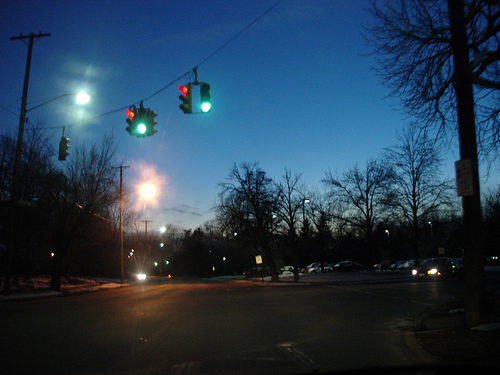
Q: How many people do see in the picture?
A: None.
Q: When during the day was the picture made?
A: At night.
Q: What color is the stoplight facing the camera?
A: Green.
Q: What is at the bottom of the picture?
A: A road.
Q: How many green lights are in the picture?
A: Two.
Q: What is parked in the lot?
A: Automobiles.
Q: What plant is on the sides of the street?
A: Trees.